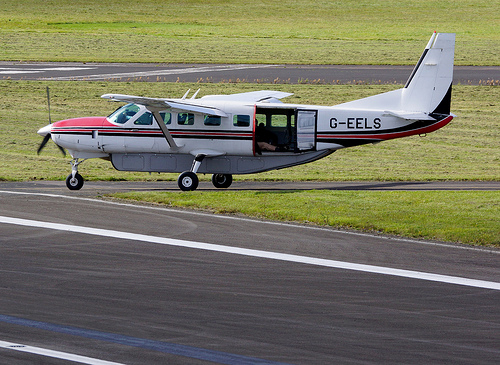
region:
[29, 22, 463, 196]
red and white single engine plane on runway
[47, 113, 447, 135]
red stripes painted on white plane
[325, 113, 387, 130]
black letters G-EELS on side of plane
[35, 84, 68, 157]
propeller on front of plane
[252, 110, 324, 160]
open door on side of plane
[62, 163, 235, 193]
three airplane wheels on bottom of plane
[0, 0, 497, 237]
green grassy field in between airfield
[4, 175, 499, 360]
grey concrete tarmac in airfield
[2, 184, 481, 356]
white and blue lines on grey runway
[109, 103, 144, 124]
front cockpit window on front of plane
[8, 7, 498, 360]
picture taken outside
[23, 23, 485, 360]
picture taken outdoors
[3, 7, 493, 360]
picture taken during the day time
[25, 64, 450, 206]
a propeller plane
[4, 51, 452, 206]
the plane is on the ground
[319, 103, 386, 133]
the letters g-eels on the plane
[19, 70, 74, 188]
the propeller is not moving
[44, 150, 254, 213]
the wheels are on the ground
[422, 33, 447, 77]
the tail is white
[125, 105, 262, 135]
windows on the plane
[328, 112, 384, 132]
writing on the side of the plane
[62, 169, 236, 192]
the wheels of the plane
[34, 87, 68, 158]
the front rotor of the plane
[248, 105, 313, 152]
the open plane door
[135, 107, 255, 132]
windows alongside the plane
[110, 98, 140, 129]
the front window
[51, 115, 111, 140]
red paint of the front of the plane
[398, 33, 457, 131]
the tail wing of the plane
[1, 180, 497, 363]
a cement runway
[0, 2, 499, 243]
green grass around the runway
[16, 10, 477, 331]
The plane is making a landing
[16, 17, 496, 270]
A plane has landed at the airport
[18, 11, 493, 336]
The door is open on an airplane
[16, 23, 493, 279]
The plane is bringing some passengers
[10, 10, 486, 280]
The plane is a propeller driven aircraft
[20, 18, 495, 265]
The plane landed close to the grass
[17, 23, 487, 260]
The plane belongs to a local businessman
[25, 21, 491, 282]
The plane is taxiing very safely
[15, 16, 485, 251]
The small plane is privately owned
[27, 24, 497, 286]
The plane is operating in daytime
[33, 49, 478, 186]
A plane on the runway.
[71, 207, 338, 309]
A white line on the runway.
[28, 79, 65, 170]
Propeller in front of the plane.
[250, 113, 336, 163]
The door is open on the plane.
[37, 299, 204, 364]
A blue line on the runway.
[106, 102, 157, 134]
Cockpit of the plane.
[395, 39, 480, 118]
The tail of the plane.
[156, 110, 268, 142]
Windows on the plane.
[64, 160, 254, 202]
Landing gear of the plane.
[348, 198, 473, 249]
Grass on the side of the runway.